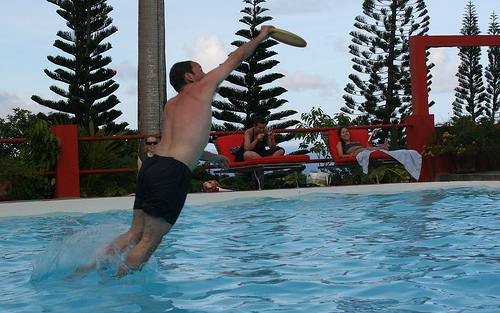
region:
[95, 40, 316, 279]
the man in the pool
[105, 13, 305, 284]
the man catching the frisbee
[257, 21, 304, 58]
the frisbee is yellow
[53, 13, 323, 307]
the man is jumping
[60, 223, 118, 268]
the water is splashing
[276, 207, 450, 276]
ripples in the water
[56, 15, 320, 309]
the man is wet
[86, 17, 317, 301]
the man wearing shorts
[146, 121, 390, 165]
people beside the pool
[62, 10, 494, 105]
trees beside the pool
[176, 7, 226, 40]
this is the sky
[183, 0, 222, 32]
the sky is blue in color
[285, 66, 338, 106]
the sky has some clouds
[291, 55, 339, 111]
the clouds are white in color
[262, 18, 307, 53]
this is a frisbey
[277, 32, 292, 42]
the frisbey is white in color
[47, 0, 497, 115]
these are some trees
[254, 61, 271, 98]
the leaves are green in color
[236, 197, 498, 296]
this is a pool of water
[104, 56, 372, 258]
these are three people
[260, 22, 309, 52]
frisbee pool toy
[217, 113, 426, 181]
two people poolside on chaise lounges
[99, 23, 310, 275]
a man jumping up out of the water to catch a frisbee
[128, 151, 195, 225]
male swim trunks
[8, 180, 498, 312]
a swimming pool with bright clean blue water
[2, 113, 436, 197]
fence around the side of the pool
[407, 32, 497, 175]
entryway to the pool area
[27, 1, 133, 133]
a tree outside of the pool area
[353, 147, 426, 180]
a white pool towel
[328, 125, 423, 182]
woman in a bathing suit lounging by the poolside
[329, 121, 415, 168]
a lady relaxing on abed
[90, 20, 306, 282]
a man cstching a frisbee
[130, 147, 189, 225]
black wet shorts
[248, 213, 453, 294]
the water is calm and blue in colour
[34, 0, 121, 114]
pine tree growin on the poolside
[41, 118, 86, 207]
a red mettalic post and railiing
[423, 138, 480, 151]
yellow bright flowers growing from a plant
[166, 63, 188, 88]
black natly kept hair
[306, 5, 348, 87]
the sky is cloudy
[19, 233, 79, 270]
waves caused by movement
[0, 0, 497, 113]
blue of daytime sky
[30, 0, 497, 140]
tall trees with needles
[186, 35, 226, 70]
white cloud in sky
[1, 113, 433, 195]
fence with two red poles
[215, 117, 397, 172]
two people on chairs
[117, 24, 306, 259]
man reaching for frisbee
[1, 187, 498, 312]
reflection on pool of water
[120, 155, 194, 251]
swim trunks on legs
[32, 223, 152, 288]
water splash around legs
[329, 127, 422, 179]
red chair with white towel